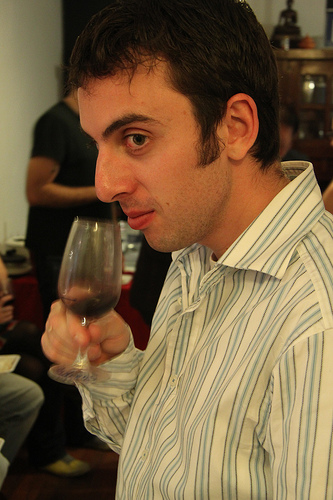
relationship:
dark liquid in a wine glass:
[66, 291, 118, 322] [48, 216, 123, 386]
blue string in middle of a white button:
[171, 378, 175, 383] [168, 374, 180, 387]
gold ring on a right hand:
[47, 324, 55, 335] [42, 284, 132, 370]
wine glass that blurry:
[48, 216, 123, 386] [69, 215, 120, 242]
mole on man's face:
[164, 199, 173, 209] [78, 109, 198, 254]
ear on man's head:
[224, 90, 260, 162] [66, 0, 282, 253]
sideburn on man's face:
[195, 100, 228, 167] [78, 109, 198, 254]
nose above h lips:
[93, 143, 138, 204] [122, 206, 158, 231]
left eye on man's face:
[120, 126, 156, 156] [78, 109, 198, 254]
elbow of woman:
[22, 180, 52, 207] [24, 67, 127, 329]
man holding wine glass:
[40, 0, 332, 499] [48, 216, 123, 386]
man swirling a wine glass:
[40, 0, 332, 499] [48, 216, 123, 386]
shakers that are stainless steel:
[300, 72, 329, 104] [306, 90, 312, 97]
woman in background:
[24, 67, 127, 329] [1, 1, 333, 499]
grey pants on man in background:
[1, 369, 47, 465] [0, 333, 47, 499]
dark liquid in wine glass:
[66, 291, 118, 322] [48, 216, 123, 386]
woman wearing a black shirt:
[24, 67, 127, 329] [24, 101, 119, 258]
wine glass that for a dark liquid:
[48, 216, 123, 386] [66, 291, 118, 322]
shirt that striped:
[49, 160, 333, 500] [193, 397, 244, 499]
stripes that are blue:
[292, 334, 326, 498] [301, 335, 321, 496]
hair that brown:
[62, 0, 280, 177] [219, 28, 254, 64]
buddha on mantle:
[270, 1, 305, 48] [270, 49, 332, 184]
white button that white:
[168, 374, 180, 387] [172, 373, 178, 379]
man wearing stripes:
[40, 0, 332, 499] [292, 334, 326, 498]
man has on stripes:
[40, 0, 332, 499] [292, 334, 326, 498]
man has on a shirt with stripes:
[40, 0, 332, 499] [292, 334, 326, 498]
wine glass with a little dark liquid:
[48, 216, 123, 386] [66, 291, 118, 322]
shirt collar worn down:
[169, 159, 329, 281] [171, 159, 324, 280]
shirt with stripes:
[49, 160, 333, 500] [292, 334, 326, 498]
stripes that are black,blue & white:
[292, 334, 326, 498] [225, 406, 248, 448]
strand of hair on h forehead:
[127, 62, 137, 97] [78, 60, 170, 128]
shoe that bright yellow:
[42, 449, 92, 478] [54, 462, 63, 470]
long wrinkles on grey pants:
[1, 384, 45, 417] [1, 369, 47, 465]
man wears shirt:
[40, 0, 332, 499] [66, 176, 315, 476]